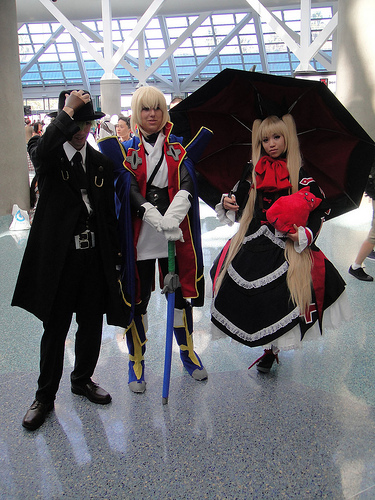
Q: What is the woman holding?
A: Umbrella.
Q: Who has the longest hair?
A: Girl on the right.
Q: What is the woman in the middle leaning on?
A: Fake sword.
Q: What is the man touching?
A: Hat.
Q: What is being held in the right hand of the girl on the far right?
A: Umbrella.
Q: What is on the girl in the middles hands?
A: White gloves.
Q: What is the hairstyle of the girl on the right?
A: Pigtails.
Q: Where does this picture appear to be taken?
A: Airport.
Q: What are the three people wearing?
A: Costumes.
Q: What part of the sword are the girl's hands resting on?
A: Handle.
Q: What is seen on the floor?
A: Reflection.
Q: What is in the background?
A: Windows.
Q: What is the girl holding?
A: Umbrella.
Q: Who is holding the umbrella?
A: Girl.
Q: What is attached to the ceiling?
A: Beams.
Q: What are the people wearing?
A: Costumes.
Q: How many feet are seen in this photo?
A: Six.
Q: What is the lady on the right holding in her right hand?
A: Umbrella.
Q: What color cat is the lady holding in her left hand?
A: Red.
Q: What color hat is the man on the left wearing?
A: Black.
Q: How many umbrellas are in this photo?
A: One.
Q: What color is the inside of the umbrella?
A: Maroon.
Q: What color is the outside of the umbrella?
A: Black.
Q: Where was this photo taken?
A: At a costume event.